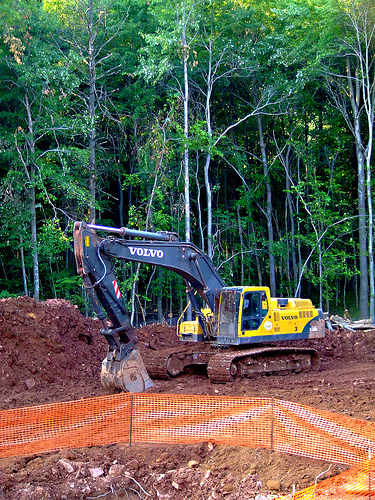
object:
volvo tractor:
[71, 220, 326, 393]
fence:
[0, 388, 374, 498]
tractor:
[71, 220, 327, 393]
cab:
[214, 285, 273, 346]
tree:
[133, 1, 204, 320]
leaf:
[167, 39, 172, 43]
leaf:
[140, 34, 144, 38]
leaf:
[159, 8, 165, 11]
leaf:
[197, 20, 199, 23]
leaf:
[140, 56, 143, 58]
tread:
[205, 345, 321, 383]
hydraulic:
[84, 223, 170, 240]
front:
[175, 286, 243, 346]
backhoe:
[70, 219, 326, 392]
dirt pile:
[0, 295, 361, 400]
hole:
[1, 444, 352, 498]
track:
[143, 342, 218, 380]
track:
[206, 345, 322, 382]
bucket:
[99, 347, 155, 392]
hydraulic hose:
[71, 217, 115, 285]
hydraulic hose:
[105, 232, 224, 286]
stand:
[1, 2, 363, 326]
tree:
[128, 0, 211, 321]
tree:
[221, 0, 285, 295]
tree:
[264, 0, 362, 317]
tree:
[2, 0, 57, 300]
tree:
[39, 0, 133, 318]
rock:
[87, 467, 104, 479]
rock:
[58, 456, 74, 472]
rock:
[68, 482, 76, 488]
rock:
[185, 458, 199, 468]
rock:
[170, 479, 184, 490]